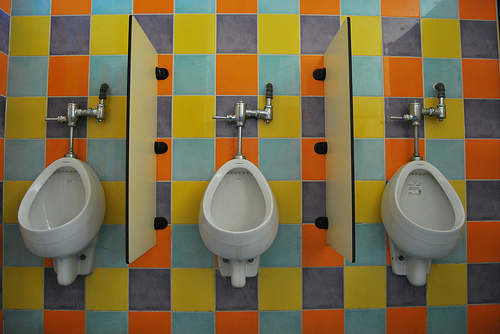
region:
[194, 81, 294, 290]
urinal is against the wall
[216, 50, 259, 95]
square is orange color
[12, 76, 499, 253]
there are 3 urinals in picture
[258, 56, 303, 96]
square is blue in color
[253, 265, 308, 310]
square is yellow in color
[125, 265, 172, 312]
square is purple in color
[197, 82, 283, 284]
urinal is white in color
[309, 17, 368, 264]
divider is yellow and black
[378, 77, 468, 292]
urinal looks clean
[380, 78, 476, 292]
urinal is oval in shape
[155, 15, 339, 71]
The wall is multi colored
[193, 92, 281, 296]
The urinal on the wall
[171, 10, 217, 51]
The color is called mustard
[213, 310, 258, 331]
The color is called orange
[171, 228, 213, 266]
The color is light blue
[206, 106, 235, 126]
The handle to flush the toilet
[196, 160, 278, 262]
The urinal is the color white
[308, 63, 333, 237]
The latches on the wall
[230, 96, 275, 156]
The pipe to the toilet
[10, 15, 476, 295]
a bunch of white urinals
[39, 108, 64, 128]
the flusher of a urinal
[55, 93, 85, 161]
the pipe of a urinal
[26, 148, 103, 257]
the pot of a urinal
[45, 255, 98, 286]
the base of a urinal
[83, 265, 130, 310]
a yellow colored tile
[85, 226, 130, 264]
a light blue colored tile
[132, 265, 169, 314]
a dark blue colored tile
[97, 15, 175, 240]
the wall of a stall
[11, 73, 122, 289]
white toilet urinal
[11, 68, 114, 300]
white toilet urinal with silver fixtures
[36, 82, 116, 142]
chrome fixture on a wall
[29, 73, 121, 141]
chrome toilet fixture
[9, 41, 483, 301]
three white toilet urinals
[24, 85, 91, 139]
a silver toilet flash handle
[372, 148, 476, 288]
A white clean urinal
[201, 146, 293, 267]
A white clean urinal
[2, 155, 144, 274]
A white clean urinal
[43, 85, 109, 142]
A silver water flusher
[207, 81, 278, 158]
A silver water flusher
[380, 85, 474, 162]
A silver water flusher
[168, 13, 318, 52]
A yellow blue and orange wall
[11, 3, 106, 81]
A yellow blue and orange wall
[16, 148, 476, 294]
three urinals in wall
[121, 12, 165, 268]
light colored urinal divider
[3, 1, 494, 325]
yellow purple and orange squares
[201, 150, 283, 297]
white ceramic urinal in wall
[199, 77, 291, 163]
stainless steel urinal handle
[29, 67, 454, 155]
three stainless steel handles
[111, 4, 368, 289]
urinal in between two dividers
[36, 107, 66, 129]
handle used to flush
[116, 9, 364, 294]
two dividers around urinal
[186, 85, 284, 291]
white urinal with silver plumbing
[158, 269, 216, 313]
A tile in a floor.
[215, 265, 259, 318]
A tile in a floor.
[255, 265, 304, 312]
A tile in a floor.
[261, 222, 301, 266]
A tile in a floor.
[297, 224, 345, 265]
A tile in a floor.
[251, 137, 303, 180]
A tile in a floor.